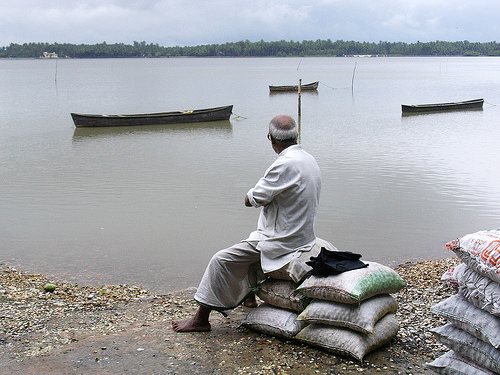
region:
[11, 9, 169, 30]
this is the sky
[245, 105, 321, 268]
this is a man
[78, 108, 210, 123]
this is a boat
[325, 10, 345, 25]
the sky is blue in color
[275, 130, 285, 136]
the man has a grey hair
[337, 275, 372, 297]
this is a sack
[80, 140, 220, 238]
this is a lake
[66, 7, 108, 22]
these are the clouds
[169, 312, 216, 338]
the man is barefooted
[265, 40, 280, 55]
this is a tree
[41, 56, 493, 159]
three canoes in the water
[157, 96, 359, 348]
a man sitting on some packages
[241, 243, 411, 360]
a stack of packages sitting on the beach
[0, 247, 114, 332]
a rocky beach meeting the water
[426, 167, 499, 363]
a stack of packages with red writing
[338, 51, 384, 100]
docking poles the middle of a water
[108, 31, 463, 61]
green foliage on the opposite shore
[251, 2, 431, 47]
gray clouds the background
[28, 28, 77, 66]
a large home on the opposite shore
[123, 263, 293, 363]
the man going barefoot on the beach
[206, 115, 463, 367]
Man sitting on bags.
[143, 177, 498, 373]
Bags under the man.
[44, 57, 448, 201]
Boats in the water.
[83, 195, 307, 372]
Stones by the water.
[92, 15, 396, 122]
Trees by the water.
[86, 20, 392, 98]
Sky behind the trees.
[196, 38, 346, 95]
Green trees on the shore.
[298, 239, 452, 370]
Three stacked bags.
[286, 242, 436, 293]
Black item on the bags.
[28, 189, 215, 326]
Where the water meets the shore.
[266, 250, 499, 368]
White sacks are arranged in sand.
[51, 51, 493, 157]
Three boats are in water.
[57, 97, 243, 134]
Boats are brown color.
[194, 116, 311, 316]
One man is sitting on the sacks.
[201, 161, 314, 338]
Old man is in white dress.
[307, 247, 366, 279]
Umbrella is black color.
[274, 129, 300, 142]
Hair is white color.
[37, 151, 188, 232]
Water is brown color.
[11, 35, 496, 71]
Trees are found behind the water.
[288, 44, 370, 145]
Poles are seen in water.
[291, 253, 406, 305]
a sack of potatoes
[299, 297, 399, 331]
a sack of potatoes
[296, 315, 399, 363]
a sack of potatoes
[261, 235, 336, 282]
a sack of potatoes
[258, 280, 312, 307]
a sack of potatoes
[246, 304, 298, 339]
a sack of potatoes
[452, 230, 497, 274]
a sack of potatoes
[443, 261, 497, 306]
a sack of potatoes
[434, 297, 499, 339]
a sack of potatoes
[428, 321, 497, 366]
a sack of potatoes